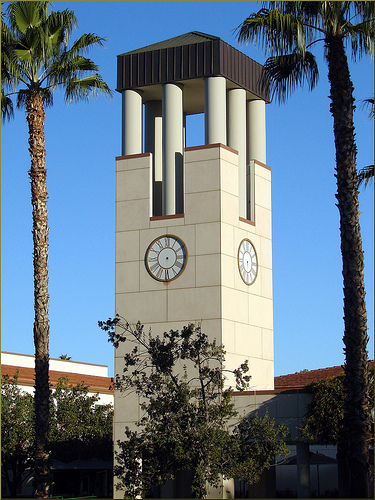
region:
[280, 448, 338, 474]
an umbrella next to a building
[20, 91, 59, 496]
the trunk of a palm tree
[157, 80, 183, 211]
a white column on the top of a clock tower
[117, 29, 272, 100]
a roof on the top of a clock tower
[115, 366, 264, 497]
a tree in front of a clock tower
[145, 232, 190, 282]
a clock face in a clock tower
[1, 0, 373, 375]
a blue sky behind a clock tower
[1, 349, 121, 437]
a white and brown building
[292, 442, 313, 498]
a pillar on a building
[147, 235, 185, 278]
Roman numerals on a clock face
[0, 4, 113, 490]
a tall palm tree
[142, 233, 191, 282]
a clock face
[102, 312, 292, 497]
a green tree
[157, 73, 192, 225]
a white pillar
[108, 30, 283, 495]
a clock tower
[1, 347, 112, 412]
a brown tile roof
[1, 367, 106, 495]
a group of trees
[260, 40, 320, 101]
a palm leaf on a tree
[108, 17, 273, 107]
a roof covering a clock tower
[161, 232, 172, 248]
a roman numeral on a clock face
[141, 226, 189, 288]
a clock on the side of a clock tower.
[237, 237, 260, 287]
a clock facing the right.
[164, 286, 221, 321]
a large brick on a clock tower.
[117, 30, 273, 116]
a pyramid on a clock tower.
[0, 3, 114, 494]
a palm tree near a clock tower.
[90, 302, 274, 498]
a leafy green tree.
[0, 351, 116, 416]
a building with a brown roof.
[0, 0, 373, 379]
a crystal clear blue sky.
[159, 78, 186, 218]
a tall round pillar.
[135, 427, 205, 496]
an entrance to a clock tower.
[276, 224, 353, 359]
The sky is cloudless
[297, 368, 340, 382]
the roof is red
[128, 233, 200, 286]
the clock has no hands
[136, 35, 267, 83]
top of the tower is black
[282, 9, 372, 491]
the tree is tall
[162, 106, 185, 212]
the column is grey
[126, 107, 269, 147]
the columns are seven in total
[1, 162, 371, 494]
the scene was taken outdoors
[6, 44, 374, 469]
it is daytime in the photo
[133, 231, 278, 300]
the clocks are two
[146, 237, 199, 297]
The clock is white and gold.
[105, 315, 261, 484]
The tree is green.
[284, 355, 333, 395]
The roof is brown.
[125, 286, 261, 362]
The tower is white.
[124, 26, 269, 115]
The top is grey.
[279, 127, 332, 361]
The sky is clear.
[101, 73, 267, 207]
The pillars are white.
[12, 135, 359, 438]
The sky is shining.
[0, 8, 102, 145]
The palm tree is tall.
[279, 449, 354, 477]
THe umbrella is out.